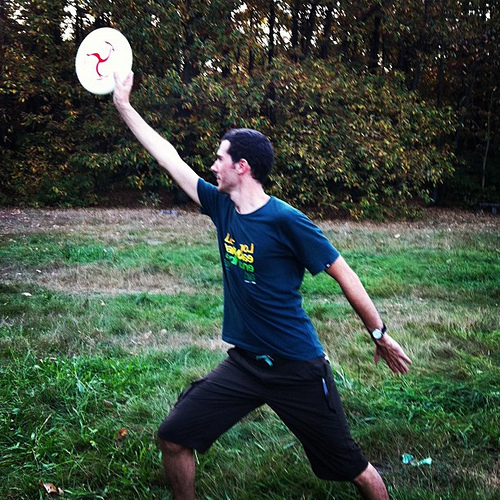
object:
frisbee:
[75, 25, 134, 95]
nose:
[210, 160, 218, 174]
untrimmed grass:
[0, 210, 500, 500]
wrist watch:
[371, 322, 388, 341]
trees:
[0, 0, 500, 206]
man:
[112, 68, 412, 500]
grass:
[4, 208, 214, 237]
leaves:
[38, 426, 127, 493]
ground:
[0, 187, 499, 498]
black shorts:
[157, 344, 371, 482]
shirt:
[195, 175, 340, 361]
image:
[85, 39, 114, 81]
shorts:
[155, 344, 370, 482]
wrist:
[369, 325, 396, 346]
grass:
[99, 347, 428, 488]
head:
[210, 128, 275, 209]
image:
[224, 232, 257, 284]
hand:
[112, 69, 136, 112]